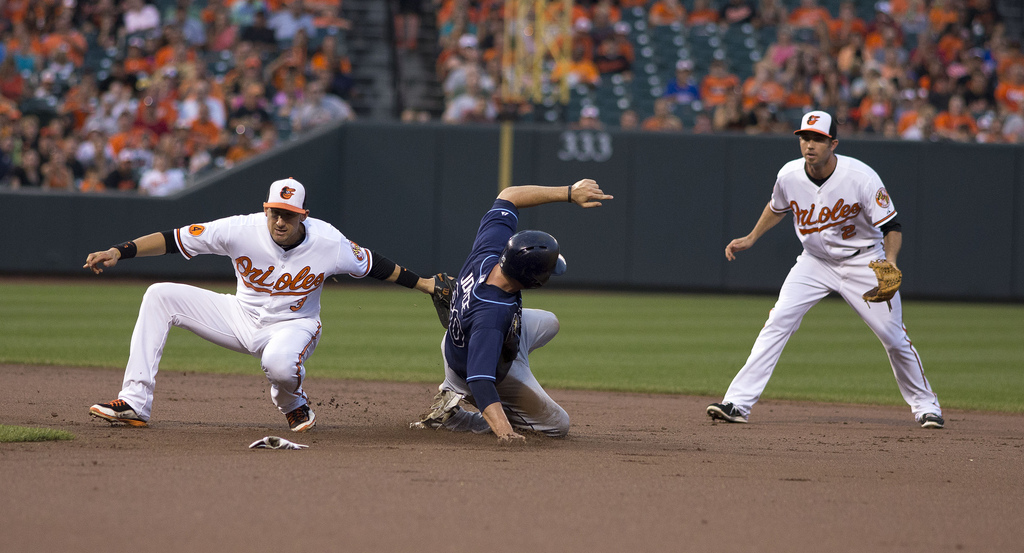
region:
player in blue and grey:
[409, 127, 625, 437]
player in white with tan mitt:
[719, 95, 986, 466]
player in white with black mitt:
[76, 167, 485, 436]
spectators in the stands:
[20, 6, 1011, 215]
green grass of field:
[7, 265, 1011, 411]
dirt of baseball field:
[4, 353, 1010, 549]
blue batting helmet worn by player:
[495, 217, 591, 287]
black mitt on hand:
[412, 256, 461, 326]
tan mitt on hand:
[835, 237, 919, 323]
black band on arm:
[87, 231, 152, 282]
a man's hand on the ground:
[478, 398, 554, 465]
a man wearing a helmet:
[509, 234, 570, 280]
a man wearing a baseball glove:
[858, 251, 904, 310]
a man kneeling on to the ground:
[89, 210, 380, 429]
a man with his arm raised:
[481, 162, 625, 248]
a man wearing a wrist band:
[115, 226, 147, 271]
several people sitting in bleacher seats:
[42, 13, 333, 150]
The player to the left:
[81, 149, 420, 538]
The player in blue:
[380, 118, 643, 450]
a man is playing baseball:
[76, 175, 447, 436]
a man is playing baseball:
[719, 101, 941, 427]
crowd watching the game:
[4, 2, 1022, 205]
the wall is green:
[0, 125, 1016, 266]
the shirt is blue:
[450, 205, 520, 392]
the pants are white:
[114, 283, 312, 407]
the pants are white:
[725, 257, 941, 425]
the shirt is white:
[175, 216, 359, 322]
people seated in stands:
[4, 1, 1022, 195]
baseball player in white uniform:
[710, 116, 941, 424]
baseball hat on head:
[266, 178, 308, 246]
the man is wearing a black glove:
[81, 167, 454, 434]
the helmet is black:
[498, 228, 566, 280]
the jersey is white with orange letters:
[171, 208, 371, 317]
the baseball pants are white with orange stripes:
[119, 279, 322, 419]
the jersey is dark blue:
[441, 199, 522, 406]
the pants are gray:
[437, 306, 567, 436]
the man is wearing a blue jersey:
[409, 177, 612, 447]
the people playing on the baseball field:
[2, 3, 1018, 551]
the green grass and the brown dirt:
[4, 265, 1022, 551]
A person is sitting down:
[698, 64, 737, 110]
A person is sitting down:
[847, 65, 880, 98]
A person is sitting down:
[922, 49, 955, 91]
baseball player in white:
[43, 143, 449, 444]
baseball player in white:
[697, 78, 980, 468]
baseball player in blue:
[367, 160, 655, 489]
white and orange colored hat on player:
[245, 162, 321, 220]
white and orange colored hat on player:
[791, 104, 842, 143]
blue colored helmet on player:
[494, 222, 580, 286]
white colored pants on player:
[78, 284, 325, 418]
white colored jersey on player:
[169, 211, 386, 332]